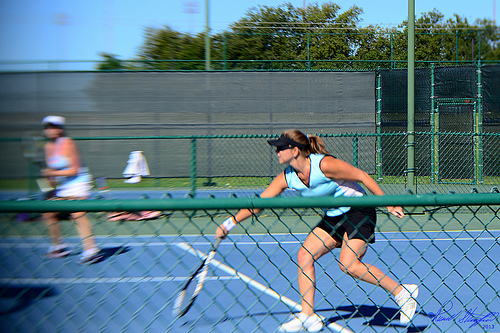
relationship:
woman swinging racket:
[211, 131, 421, 332] [174, 233, 231, 319]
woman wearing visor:
[211, 131, 421, 332] [266, 125, 295, 147]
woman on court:
[211, 131, 421, 332] [425, 242, 497, 290]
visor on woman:
[266, 125, 295, 147] [211, 131, 421, 332]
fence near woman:
[122, 205, 315, 314] [211, 131, 421, 332]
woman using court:
[211, 131, 421, 332] [425, 242, 497, 290]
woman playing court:
[211, 131, 421, 332] [425, 242, 497, 290]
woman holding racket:
[211, 131, 421, 332] [174, 233, 231, 319]